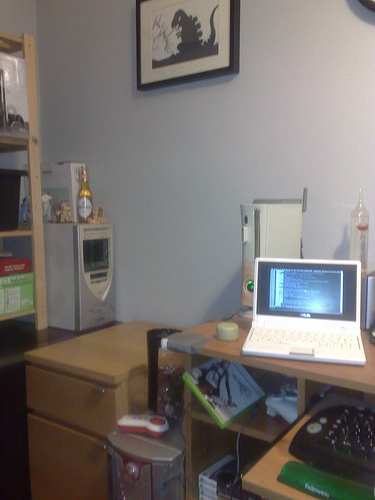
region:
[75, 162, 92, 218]
Beer bottle on top of PC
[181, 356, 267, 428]
Game next to game controller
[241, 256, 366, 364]
White laptop on top of desk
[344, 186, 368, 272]
Glass bottle behind laptop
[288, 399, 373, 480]
Black keyboard on desk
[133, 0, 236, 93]
Art frame hung on wall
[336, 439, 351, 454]
Black key on keyboard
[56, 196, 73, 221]
Figurine next to beer bottle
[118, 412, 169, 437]
Red and white toy next to cabinet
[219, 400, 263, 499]
Gray cord next to game controller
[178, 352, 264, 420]
A video game case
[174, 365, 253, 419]
The case is green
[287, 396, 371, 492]
the keyboard is black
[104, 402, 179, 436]
the remote is white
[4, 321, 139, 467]
the table is wooden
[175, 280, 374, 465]
the desk is wooden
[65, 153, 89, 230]
beer on the computer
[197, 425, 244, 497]
Other game cases below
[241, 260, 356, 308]
the computer is on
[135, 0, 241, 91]
picture in black frame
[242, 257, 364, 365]
inside of open white laptop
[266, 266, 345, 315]
glowing image on screen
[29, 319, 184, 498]
wood cabinet with drawer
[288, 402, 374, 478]
edge of black keyboard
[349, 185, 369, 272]
clear liquid in bottle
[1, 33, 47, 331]
items on wood shelves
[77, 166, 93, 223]
bottle with yellow liquid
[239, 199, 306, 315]
glowing green light on electronics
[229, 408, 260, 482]
hanging gray wire on shelf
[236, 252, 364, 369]
a white personal laptop computer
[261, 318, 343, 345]
the keyboard of a laptop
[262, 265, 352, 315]
the screen of a laptop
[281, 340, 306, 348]
the touchpad of a laptop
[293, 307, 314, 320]
the logo of a laptop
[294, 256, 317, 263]
the webcam of a laptop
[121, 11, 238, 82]
a black and white picture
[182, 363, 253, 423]
a small green and white book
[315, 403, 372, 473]
a large manual keyboard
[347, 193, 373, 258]
a small bottle of water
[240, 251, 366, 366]
An open laptop.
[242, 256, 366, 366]
A white laptop.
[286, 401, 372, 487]
A black computer keyboard.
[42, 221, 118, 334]
A computer.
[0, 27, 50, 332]
A wooden bookshelf with objects on it.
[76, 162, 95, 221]
A bottle full of yellow liquid.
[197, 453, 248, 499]
A stack of DVD cases.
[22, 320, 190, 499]
A piece of furniture.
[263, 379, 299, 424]
Video game controller.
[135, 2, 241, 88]
A picture of a dinosaur hanging on the wall.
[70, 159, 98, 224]
The bottle is gold.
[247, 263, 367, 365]
A laptop on top of the desk.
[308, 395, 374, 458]
The keyboard is black.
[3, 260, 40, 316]
Green box on the shelf.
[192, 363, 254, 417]
Book on the shelf of the desk.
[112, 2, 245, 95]
Picture on the wall.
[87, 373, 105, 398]
a lock on the cabinet.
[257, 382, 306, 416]
A game remote on the shelf.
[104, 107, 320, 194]
The wall is white.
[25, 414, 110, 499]
A door for a cabinet.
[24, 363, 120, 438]
A drawer on a cabinet